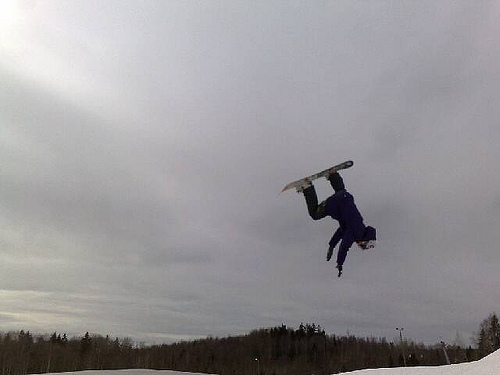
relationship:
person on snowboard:
[294, 171, 379, 280] [273, 151, 356, 193]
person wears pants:
[294, 171, 379, 280] [299, 174, 350, 219]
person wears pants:
[294, 171, 379, 280] [298, 174, 355, 221]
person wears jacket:
[294, 171, 379, 280] [327, 205, 377, 265]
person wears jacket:
[294, 171, 379, 280] [327, 196, 380, 279]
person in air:
[271, 140, 385, 293] [225, 120, 436, 307]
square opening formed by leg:
[310, 175, 335, 202] [302, 184, 329, 221]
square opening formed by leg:
[310, 175, 335, 202] [329, 171, 344, 192]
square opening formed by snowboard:
[310, 175, 335, 202] [281, 159, 354, 191]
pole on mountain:
[394, 325, 411, 370] [347, 345, 497, 374]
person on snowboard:
[294, 171, 379, 280] [280, 160, 354, 194]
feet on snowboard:
[295, 170, 337, 192] [281, 159, 354, 191]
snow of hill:
[8, 349, 496, 373] [0, 316, 499, 374]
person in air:
[294, 171, 379, 280] [36, 30, 466, 341]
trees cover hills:
[0, 320, 498, 373] [33, 296, 424, 364]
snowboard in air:
[266, 161, 379, 199] [179, 98, 430, 321]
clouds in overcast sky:
[0, 0, 498, 348] [0, 0, 497, 349]